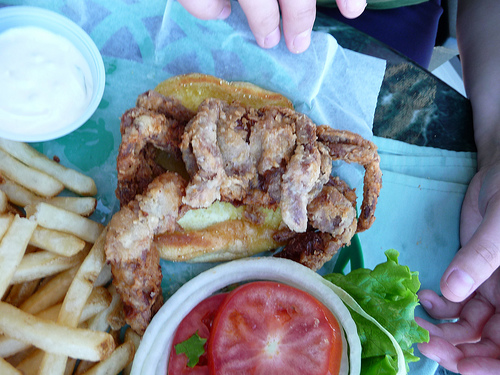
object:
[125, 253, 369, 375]
onion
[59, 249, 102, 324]
french fry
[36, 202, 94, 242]
french fry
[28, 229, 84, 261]
french fry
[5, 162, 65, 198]
french fry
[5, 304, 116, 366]
french fry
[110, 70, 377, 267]
sandwich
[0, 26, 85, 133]
condiment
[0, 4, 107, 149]
cup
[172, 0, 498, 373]
person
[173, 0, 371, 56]
hand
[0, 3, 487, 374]
table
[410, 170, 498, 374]
hand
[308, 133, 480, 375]
napkin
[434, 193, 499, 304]
thumb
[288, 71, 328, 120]
edge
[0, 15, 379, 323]
dish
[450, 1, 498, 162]
arm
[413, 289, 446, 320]
finger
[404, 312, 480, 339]
finger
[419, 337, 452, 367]
finger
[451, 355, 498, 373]
finger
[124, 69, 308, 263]
bun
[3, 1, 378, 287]
wrapper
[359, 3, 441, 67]
pants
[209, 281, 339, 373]
tomato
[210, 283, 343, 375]
slice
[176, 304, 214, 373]
tomato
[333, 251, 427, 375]
lettuce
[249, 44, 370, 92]
cloth